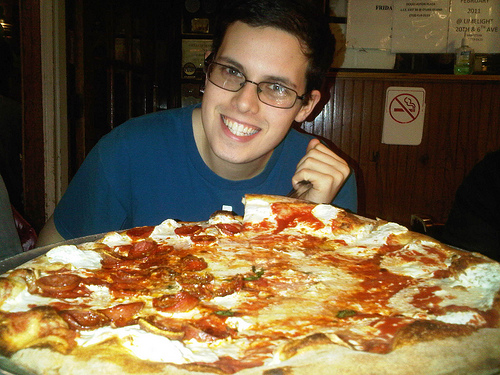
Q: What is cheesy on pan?
A: Pizza.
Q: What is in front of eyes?
A: Glasses.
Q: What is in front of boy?
A: Pizza.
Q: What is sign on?
A: Wall.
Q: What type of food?
A: Pizza.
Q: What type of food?
A: Pizza.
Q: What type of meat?
A: Pepperoni.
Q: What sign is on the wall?
A: No smoking.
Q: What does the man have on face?
A: Glasses.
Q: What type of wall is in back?
A: Brown wood paneled.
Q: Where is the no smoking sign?
A: Brown wall.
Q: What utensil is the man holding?
A: Fork.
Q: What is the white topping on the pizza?
A: Cheese.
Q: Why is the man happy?
A: Eating large pizza.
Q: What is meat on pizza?
A: Pepperoni.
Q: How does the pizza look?
A: Very large.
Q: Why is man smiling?
A: Pizza.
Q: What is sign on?
A: Wall.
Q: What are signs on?
A: Wall.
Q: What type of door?
A: Wooden.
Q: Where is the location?
A: Restaurant.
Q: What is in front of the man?
A: A large pizza.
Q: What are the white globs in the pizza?
A: Feta cheese.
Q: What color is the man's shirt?
A: Blue.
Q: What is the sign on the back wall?
A: No smoking sign.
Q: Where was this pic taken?
A: At a restaurant.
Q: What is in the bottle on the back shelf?
A: Hand sanitizer.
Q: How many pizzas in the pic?
A: 1.